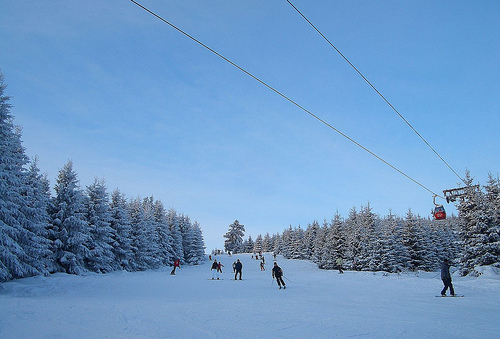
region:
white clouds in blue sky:
[15, 9, 73, 61]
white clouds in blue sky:
[12, 47, 90, 115]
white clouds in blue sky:
[69, 99, 146, 159]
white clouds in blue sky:
[145, 122, 217, 157]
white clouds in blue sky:
[223, 142, 310, 212]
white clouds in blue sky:
[142, 17, 219, 82]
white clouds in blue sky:
[270, 11, 363, 114]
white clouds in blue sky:
[377, 66, 444, 162]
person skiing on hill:
[267, 256, 292, 297]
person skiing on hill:
[222, 252, 263, 292]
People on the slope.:
[140, 218, 314, 290]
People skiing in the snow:
[169, 240, 311, 296]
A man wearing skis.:
[418, 236, 469, 304]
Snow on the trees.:
[28, 178, 165, 253]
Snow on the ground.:
[76, 280, 354, 328]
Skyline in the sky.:
[342, 138, 476, 225]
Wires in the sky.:
[259, 57, 458, 207]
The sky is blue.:
[98, 37, 398, 188]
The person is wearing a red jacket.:
[166, 253, 190, 268]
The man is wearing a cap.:
[440, 254, 458, 264]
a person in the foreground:
[436, 254, 467, 296]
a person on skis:
[269, 260, 293, 294]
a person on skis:
[231, 256, 244, 280]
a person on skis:
[209, 260, 222, 282]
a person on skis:
[168, 256, 184, 276]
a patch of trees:
[0, 73, 210, 285]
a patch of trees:
[223, 169, 497, 273]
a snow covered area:
[3, 242, 498, 334]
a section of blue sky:
[0, 0, 497, 253]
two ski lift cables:
[121, 0, 487, 215]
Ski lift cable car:
[432, 198, 447, 223]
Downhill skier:
[268, 258, 290, 290]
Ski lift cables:
[116, 3, 475, 185]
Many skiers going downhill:
[160, 250, 299, 284]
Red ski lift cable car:
[427, 190, 448, 222]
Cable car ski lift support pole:
[443, 183, 481, 210]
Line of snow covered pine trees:
[0, 119, 205, 285]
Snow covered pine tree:
[223, 217, 247, 257]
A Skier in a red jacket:
[166, 254, 186, 276]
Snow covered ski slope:
[206, 250, 341, 335]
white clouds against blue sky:
[3, 0, 127, 74]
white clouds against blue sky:
[23, 67, 118, 122]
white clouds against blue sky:
[126, 85, 216, 159]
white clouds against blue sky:
[161, 142, 263, 189]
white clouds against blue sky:
[199, 93, 311, 138]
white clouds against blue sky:
[185, 22, 325, 76]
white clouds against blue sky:
[391, 29, 466, 97]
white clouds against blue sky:
[303, 62, 370, 154]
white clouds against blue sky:
[363, 123, 428, 181]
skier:
[266, 257, 306, 299]